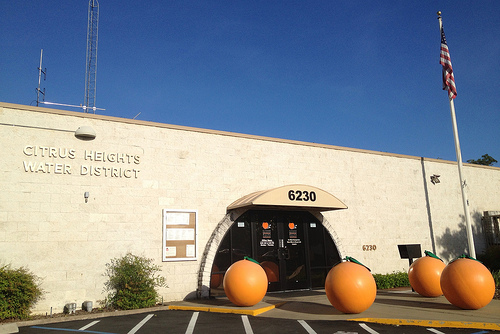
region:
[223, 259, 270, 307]
a statue of an orange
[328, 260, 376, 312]
a statue of an orange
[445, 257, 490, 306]
a statue of an orange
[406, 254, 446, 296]
a statue of an orange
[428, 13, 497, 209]
american flag on a pole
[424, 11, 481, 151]
a flag on a metal pole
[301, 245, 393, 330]
large round orange sculpture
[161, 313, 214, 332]
bold white lines on the ground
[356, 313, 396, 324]
yellow paint on edge of wall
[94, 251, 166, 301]
small cluster of green bush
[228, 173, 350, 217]
oval shaped pink overhang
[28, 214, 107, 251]
white paint on wall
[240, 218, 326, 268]
large section of glass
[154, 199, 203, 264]
small brown announcement board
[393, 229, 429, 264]
small black mailbox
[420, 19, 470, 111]
flag of United States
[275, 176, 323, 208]
the number is 6230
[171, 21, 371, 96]
bright clear blue skies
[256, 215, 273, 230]
orange sign on door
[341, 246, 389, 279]
green leaf on object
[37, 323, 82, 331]
thin blue line on ground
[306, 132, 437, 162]
brown edge of roof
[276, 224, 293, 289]
black frame on door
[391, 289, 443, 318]
shadow cast on the ground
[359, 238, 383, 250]
number on side of wall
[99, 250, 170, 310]
cluster of green bush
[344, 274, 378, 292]
shiny surface of object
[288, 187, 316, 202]
the numbers 6230 on the building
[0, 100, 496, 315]
the large light colored building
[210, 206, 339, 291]
the glass in front of the building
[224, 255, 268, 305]
the over sized orange in front of the building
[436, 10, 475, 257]
the tall flag pole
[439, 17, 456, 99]
the flag on the pole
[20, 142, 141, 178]
the words on the building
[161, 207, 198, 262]
the bulletin board on the building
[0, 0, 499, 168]
the blue sky above the building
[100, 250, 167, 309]
the bush in front of the building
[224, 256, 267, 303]
a giant orange fruit statue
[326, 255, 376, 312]
a giant orange fruit statue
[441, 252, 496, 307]
a giant orange fruit statue